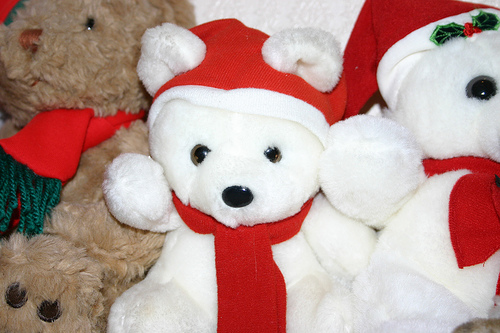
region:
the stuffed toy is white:
[133, 68, 248, 316]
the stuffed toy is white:
[188, 69, 310, 314]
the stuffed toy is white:
[250, 166, 418, 331]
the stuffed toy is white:
[226, 123, 358, 328]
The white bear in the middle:
[94, 13, 377, 332]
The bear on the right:
[319, 1, 498, 331]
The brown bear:
[1, 0, 193, 331]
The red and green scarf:
[1, 102, 149, 239]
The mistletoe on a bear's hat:
[431, 8, 498, 47]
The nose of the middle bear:
[221, 180, 257, 213]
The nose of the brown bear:
[14, 23, 47, 54]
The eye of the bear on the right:
[461, 65, 498, 112]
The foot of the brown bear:
[1, 231, 101, 332]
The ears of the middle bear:
[135, 19, 345, 98]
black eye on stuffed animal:
[257, 140, 289, 169]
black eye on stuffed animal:
[182, 138, 213, 172]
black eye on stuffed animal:
[463, 71, 496, 108]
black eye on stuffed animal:
[35, 291, 62, 327]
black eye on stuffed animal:
[2, 281, 30, 311]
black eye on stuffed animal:
[77, 13, 102, 44]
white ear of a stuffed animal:
[255, 24, 349, 99]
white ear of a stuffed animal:
[130, 19, 205, 99]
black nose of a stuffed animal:
[217, 180, 253, 212]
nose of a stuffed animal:
[15, 24, 47, 58]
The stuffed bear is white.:
[150, 99, 305, 282]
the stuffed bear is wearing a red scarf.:
[162, 115, 307, 277]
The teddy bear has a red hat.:
[120, 17, 302, 213]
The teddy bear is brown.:
[10, 10, 130, 172]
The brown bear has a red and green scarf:
[6, 17, 86, 236]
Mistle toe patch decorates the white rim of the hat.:
[416, 10, 498, 53]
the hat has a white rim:
[147, 12, 311, 133]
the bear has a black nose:
[160, 81, 300, 223]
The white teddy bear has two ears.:
[131, 20, 337, 170]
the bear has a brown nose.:
[5, 0, 168, 170]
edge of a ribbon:
[258, 253, 280, 293]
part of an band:
[25, 186, 65, 203]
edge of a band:
[440, 154, 477, 172]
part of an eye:
[265, 150, 284, 165]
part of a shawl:
[241, 267, 271, 313]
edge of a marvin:
[236, 91, 291, 112]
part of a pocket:
[290, 257, 308, 313]